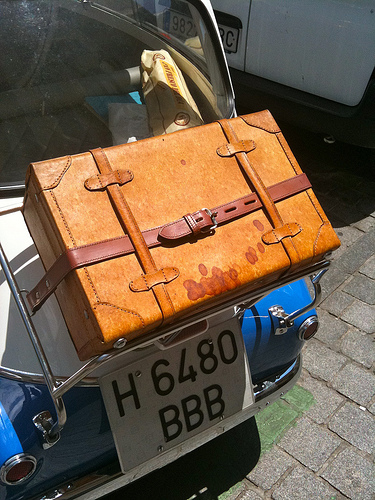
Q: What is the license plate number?
A: H 6480 BBB.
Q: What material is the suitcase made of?
A: Leather.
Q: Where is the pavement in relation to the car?
A: Underneath it.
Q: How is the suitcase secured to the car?
A: With a strap.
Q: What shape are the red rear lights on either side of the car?
A: Circles.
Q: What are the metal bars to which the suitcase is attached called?
A: A luggage rack.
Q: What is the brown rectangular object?
A: A suitcase.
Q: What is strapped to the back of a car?
A: A brown suitcase.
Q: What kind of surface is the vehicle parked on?
A: Brick.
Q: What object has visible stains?
A: The suitcase.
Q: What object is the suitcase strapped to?
A: A car.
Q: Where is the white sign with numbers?
A: On the back of the car.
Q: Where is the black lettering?
A: On the license plate.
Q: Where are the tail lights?
A: On the back of the car.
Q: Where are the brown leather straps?
A: Around the suitcase.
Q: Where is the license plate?
A: On the bumper.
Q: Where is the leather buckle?
A: Suitcase strap.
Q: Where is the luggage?
A: On the back of a car.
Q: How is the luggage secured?
A: With a brown belt.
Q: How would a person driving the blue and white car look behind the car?
A: Through the large rear window.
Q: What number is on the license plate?
A: H 6480 BBB.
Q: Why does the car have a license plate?
A: For people to identify the driver of the vehicle.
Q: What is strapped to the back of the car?
A: A brown luggage.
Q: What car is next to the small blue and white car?
A: A white van.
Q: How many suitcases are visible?
A: One.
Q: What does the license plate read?
A: H 6480 BBB.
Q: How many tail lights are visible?
A: Two.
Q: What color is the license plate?
A: White.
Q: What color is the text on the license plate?
A: Black.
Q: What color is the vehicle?
A: Blue.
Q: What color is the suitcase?
A: Brown.